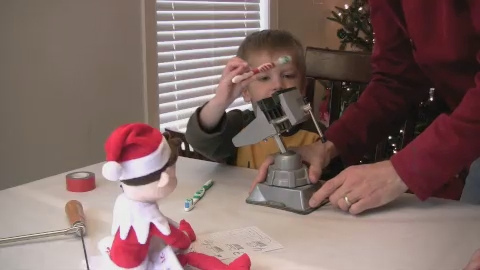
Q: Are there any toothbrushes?
A: Yes, there is a toothbrush.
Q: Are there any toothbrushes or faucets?
A: Yes, there is a toothbrush.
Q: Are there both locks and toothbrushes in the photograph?
A: No, there is a toothbrush but no locks.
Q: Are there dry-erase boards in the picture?
A: No, there are no dry-erase boards.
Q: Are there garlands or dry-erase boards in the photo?
A: No, there are no dry-erase boards or garlands.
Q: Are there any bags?
A: No, there are no bags.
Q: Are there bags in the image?
A: No, there are no bags.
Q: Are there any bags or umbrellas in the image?
A: No, there are no bags or umbrellas.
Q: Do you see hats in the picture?
A: Yes, there is a hat.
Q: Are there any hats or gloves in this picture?
A: Yes, there is a hat.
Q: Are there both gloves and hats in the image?
A: No, there is a hat but no gloves.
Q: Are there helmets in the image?
A: No, there are no helmets.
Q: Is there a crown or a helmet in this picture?
A: No, there are no helmets or crowns.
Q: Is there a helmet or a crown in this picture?
A: No, there are no helmets or crowns.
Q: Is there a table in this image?
A: Yes, there is a table.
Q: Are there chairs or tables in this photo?
A: Yes, there is a table.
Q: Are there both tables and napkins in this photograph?
A: No, there is a table but no napkins.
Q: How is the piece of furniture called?
A: The piece of furniture is a table.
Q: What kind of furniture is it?
A: The piece of furniture is a table.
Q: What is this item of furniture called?
A: This is a table.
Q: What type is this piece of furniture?
A: This is a table.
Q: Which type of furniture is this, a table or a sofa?
A: This is a table.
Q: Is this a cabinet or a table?
A: This is a table.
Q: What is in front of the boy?
A: The table is in front of the boy.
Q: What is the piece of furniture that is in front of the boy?
A: The piece of furniture is a table.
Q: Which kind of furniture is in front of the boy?
A: The piece of furniture is a table.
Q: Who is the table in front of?
A: The table is in front of the boy.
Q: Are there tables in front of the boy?
A: Yes, there is a table in front of the boy.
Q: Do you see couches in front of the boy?
A: No, there is a table in front of the boy.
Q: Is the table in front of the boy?
A: Yes, the table is in front of the boy.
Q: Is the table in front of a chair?
A: No, the table is in front of the boy.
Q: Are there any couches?
A: No, there are no couches.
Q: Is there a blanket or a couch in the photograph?
A: No, there are no couches or blankets.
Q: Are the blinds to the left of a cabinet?
A: No, the blinds are to the left of a toothbrush.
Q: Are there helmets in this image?
A: No, there are no helmets.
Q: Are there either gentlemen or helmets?
A: No, there are no helmets or gentlemen.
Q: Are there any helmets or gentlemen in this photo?
A: No, there are no helmets or gentlemen.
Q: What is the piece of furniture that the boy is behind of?
A: The piece of furniture is a table.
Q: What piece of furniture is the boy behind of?
A: The boy is behind the table.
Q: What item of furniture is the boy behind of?
A: The boy is behind the table.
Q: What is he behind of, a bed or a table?
A: The boy is behind a table.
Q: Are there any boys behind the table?
A: Yes, there is a boy behind the table.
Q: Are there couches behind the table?
A: No, there is a boy behind the table.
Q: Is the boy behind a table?
A: Yes, the boy is behind a table.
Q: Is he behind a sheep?
A: No, the boy is behind a table.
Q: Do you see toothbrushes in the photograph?
A: Yes, there is a toothbrush.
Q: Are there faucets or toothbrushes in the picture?
A: Yes, there is a toothbrush.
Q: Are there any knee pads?
A: No, there are no knee pads.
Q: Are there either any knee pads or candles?
A: No, there are no knee pads or candles.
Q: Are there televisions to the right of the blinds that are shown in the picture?
A: No, there is a toothbrush to the right of the blinds.